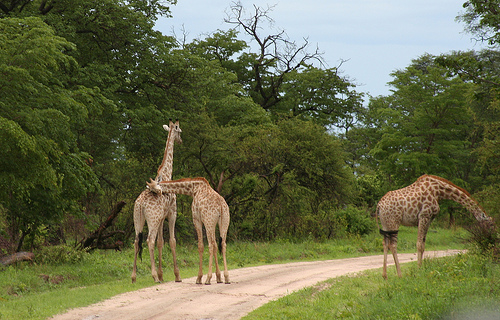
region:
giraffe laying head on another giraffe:
[143, 167, 265, 290]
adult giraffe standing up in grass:
[123, 113, 186, 288]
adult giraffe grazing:
[368, 162, 497, 295]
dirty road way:
[92, 244, 482, 315]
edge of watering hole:
[411, 270, 496, 315]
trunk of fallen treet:
[4, 167, 177, 282]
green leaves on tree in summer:
[253, 90, 340, 260]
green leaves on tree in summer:
[13, 23, 108, 252]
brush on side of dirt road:
[242, 236, 386, 269]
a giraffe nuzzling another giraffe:
[118, 114, 245, 290]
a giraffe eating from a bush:
[368, 167, 495, 277]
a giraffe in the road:
[137, 165, 254, 290]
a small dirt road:
[43, 230, 497, 317]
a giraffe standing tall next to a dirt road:
[121, 107, 191, 292]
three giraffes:
[118, 114, 498, 289]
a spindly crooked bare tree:
[204, 0, 352, 132]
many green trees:
[1, 0, 391, 259]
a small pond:
[403, 277, 488, 309]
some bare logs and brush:
[2, 181, 153, 287]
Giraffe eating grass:
[363, 152, 498, 290]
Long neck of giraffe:
[440, 178, 481, 216]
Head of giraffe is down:
[459, 196, 499, 248]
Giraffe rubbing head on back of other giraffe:
[138, 168, 240, 289]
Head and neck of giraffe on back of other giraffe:
[142, 170, 204, 197]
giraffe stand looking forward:
[121, 110, 193, 296]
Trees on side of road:
[0, 0, 498, 206]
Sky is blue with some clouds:
[177, 0, 480, 72]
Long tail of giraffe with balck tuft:
[131, 192, 146, 265]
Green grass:
[328, 249, 499, 308]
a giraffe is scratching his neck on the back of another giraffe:
[146, 177, 230, 285]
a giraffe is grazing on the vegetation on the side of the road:
[375, 173, 499, 283]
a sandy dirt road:
[48, 247, 468, 319]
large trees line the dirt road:
[0, 0, 499, 252]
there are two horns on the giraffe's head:
[143, 177, 154, 187]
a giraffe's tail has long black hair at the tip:
[133, 198, 149, 264]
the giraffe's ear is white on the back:
[161, 124, 173, 131]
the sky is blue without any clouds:
[1, 0, 499, 131]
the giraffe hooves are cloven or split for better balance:
[173, 267, 182, 282]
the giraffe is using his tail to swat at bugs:
[374, 202, 399, 242]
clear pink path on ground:
[123, 234, 325, 299]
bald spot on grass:
[300, 275, 354, 310]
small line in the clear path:
[223, 286, 278, 306]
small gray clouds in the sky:
[333, 10, 423, 54]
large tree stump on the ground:
[5, 239, 55, 266]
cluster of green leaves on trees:
[18, 105, 96, 163]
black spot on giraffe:
[365, 217, 439, 249]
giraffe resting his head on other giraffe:
[133, 170, 248, 216]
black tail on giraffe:
[130, 228, 168, 275]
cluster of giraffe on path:
[124, 93, 489, 298]